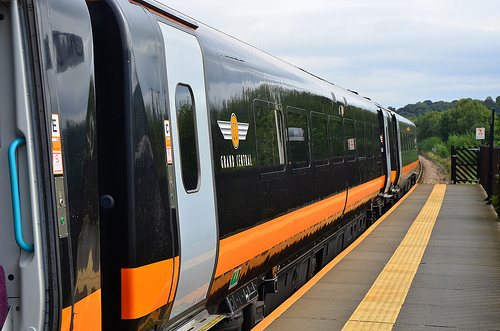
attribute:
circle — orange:
[230, 114, 239, 150]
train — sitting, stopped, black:
[1, 0, 420, 329]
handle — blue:
[9, 136, 34, 252]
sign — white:
[476, 127, 486, 141]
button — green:
[60, 216, 65, 224]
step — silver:
[164, 308, 227, 331]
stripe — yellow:
[338, 183, 447, 331]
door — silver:
[158, 21, 218, 320]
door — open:
[1, 1, 61, 331]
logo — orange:
[216, 113, 250, 151]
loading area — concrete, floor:
[247, 183, 500, 329]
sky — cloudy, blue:
[152, 1, 498, 110]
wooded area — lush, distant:
[397, 96, 500, 157]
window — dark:
[285, 111, 310, 168]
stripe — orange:
[60, 161, 420, 331]